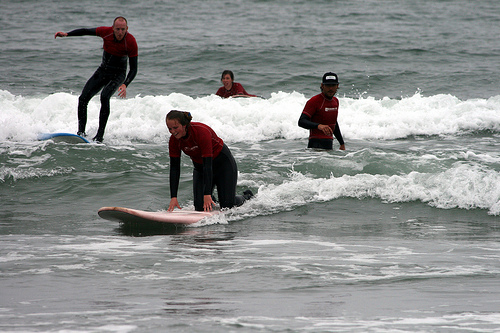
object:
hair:
[220, 70, 235, 81]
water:
[213, 2, 268, 48]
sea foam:
[0, 88, 51, 139]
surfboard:
[97, 206, 223, 225]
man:
[297, 71, 348, 151]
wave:
[449, 167, 500, 208]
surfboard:
[37, 132, 90, 143]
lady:
[164, 109, 256, 213]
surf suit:
[65, 26, 139, 144]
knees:
[194, 203, 205, 211]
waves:
[262, 173, 334, 201]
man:
[53, 16, 139, 144]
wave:
[227, 100, 290, 142]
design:
[325, 75, 336, 80]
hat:
[321, 71, 340, 85]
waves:
[344, 174, 383, 198]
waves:
[107, 121, 156, 137]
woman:
[215, 69, 266, 101]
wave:
[161, 92, 194, 110]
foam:
[348, 90, 499, 141]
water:
[357, 0, 499, 89]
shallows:
[0, 233, 500, 332]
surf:
[96, 108, 259, 226]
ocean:
[253, 219, 441, 296]